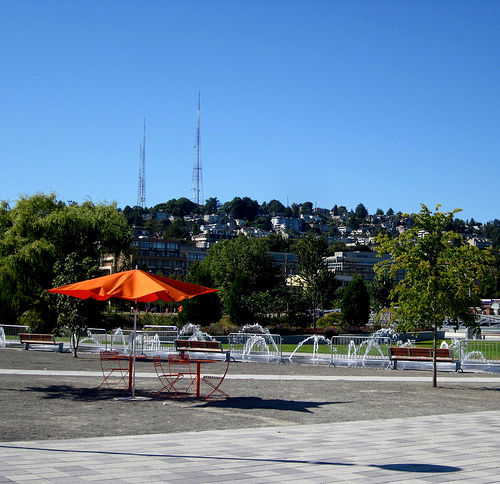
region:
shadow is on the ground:
[243, 443, 453, 480]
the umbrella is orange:
[56, 258, 213, 313]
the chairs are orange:
[101, 335, 226, 397]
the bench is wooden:
[380, 338, 457, 363]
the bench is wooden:
[11, 328, 63, 354]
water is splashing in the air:
[231, 321, 301, 359]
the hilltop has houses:
[183, 201, 396, 282]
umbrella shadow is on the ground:
[233, 378, 353, 419]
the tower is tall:
[188, 95, 210, 194]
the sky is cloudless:
[41, 43, 473, 205]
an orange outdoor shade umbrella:
[43, 260, 222, 402]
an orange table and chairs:
[99, 350, 234, 400]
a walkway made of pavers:
[0, 409, 498, 482]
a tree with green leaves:
[370, 200, 498, 388]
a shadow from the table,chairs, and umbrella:
[190, 390, 354, 414]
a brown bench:
[15, 331, 65, 353]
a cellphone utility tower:
[190, 88, 205, 203]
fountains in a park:
[0, 323, 498, 371]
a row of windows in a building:
[129, 236, 184, 251]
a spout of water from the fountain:
[242, 334, 269, 359]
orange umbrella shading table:
[52, 259, 229, 398]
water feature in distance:
[42, 315, 477, 369]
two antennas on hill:
[131, 90, 217, 205]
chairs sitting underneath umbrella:
[96, 345, 188, 393]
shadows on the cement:
[31, 369, 446, 478]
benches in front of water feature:
[12, 326, 463, 367]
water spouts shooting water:
[82, 327, 478, 376]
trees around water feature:
[2, 190, 479, 353]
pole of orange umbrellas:
[126, 305, 140, 354]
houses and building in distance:
[116, 200, 491, 327]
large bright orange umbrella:
[49, 256, 221, 405]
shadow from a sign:
[4, 436, 464, 480]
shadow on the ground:
[189, 385, 321, 420]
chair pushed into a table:
[89, 343, 156, 399]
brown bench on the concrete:
[382, 341, 460, 374]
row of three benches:
[17, 329, 464, 375]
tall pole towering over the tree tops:
[179, 86, 219, 206]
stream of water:
[287, 327, 338, 359]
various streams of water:
[64, 321, 499, 371]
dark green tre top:
[371, 202, 490, 337]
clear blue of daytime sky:
[4, 2, 496, 209]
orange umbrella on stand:
[55, 263, 218, 401]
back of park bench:
[387, 346, 460, 372]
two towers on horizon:
[133, 93, 206, 208]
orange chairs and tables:
[96, 349, 230, 404]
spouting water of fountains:
[63, 328, 482, 370]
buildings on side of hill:
[121, 212, 436, 279]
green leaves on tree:
[389, 207, 491, 337]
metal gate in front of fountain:
[324, 334, 395, 371]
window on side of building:
[129, 239, 179, 254]